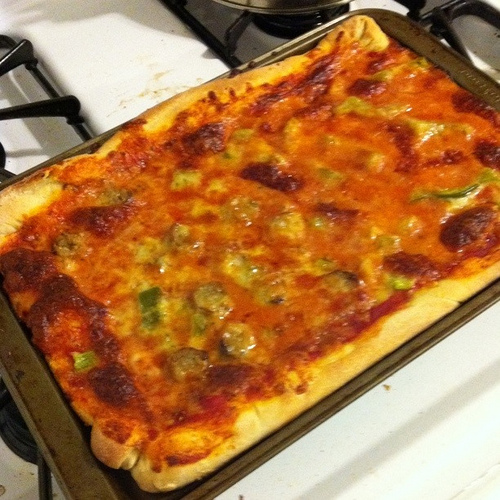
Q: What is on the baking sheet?
A: Pizza.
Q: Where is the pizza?
A: On baking sheet.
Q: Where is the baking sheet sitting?
A: A stovetop.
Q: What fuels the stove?
A: Gas.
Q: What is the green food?
A: Peppers.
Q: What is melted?
A: Cheese.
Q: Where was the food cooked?
A: Oven.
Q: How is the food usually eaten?
A: With hands.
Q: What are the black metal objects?
A: Burner grates.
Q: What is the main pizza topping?
A: Cheese.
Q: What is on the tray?
A: Pizza.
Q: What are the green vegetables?
A: Peppers.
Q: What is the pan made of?
A: Metal.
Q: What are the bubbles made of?
A: Cheese.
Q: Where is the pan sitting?
A: On a stove.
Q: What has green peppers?
A: The pizza.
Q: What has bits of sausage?
A: The pizza.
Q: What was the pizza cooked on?
A: A cookie sheet.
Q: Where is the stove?
A: Under the pizza.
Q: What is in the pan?
A: Pizza.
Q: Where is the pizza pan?
A: On a stove top.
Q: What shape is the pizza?
A: Rectangular.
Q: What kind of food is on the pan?
A: Pizza.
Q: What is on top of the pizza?
A: Cheese and peppers.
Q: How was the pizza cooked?
A: In an oven.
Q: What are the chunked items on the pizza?
A: Green pepper.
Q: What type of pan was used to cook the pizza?
A: Metal pan.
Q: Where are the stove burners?
A: On the stove top.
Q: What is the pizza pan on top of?
A: Stove burners.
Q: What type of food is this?
A: Pizza.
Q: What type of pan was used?
A: Metal pan.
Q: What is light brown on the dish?
A: Pizza crust.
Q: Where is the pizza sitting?
A: On the stove.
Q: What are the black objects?
A: Stove burners,.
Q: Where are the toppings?
A: On the pizza.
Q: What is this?
A: Food.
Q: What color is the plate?
A: Rusty brown.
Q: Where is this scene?
A: Over a stove.